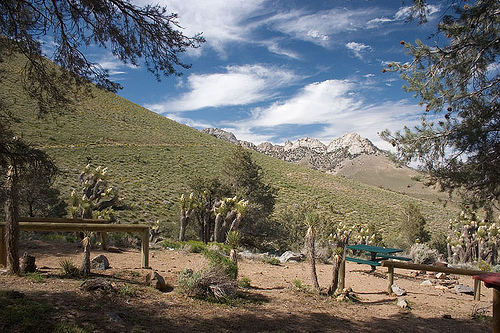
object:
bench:
[340, 244, 412, 271]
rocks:
[420, 278, 437, 286]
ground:
[5, 235, 494, 330]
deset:
[1, 2, 499, 332]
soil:
[0, 235, 498, 332]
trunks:
[298, 223, 348, 299]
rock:
[278, 249, 304, 264]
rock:
[390, 281, 408, 294]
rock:
[144, 271, 165, 288]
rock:
[89, 254, 109, 272]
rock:
[452, 284, 473, 294]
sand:
[104, 246, 492, 301]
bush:
[171, 248, 244, 303]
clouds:
[186, 57, 370, 125]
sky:
[0, 2, 498, 162]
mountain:
[273, 138, 328, 172]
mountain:
[325, 131, 372, 163]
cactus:
[75, 161, 120, 204]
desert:
[0, 41, 499, 331]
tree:
[194, 175, 233, 246]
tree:
[224, 139, 278, 241]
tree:
[398, 200, 437, 260]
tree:
[1, 0, 208, 174]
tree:
[379, 1, 499, 208]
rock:
[114, 263, 143, 278]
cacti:
[302, 225, 348, 295]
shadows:
[4, 264, 495, 330]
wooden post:
[14, 220, 153, 275]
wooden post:
[381, 259, 486, 302]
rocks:
[337, 288, 357, 304]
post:
[12, 208, 151, 273]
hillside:
[0, 36, 467, 250]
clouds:
[245, 6, 475, 66]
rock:
[395, 296, 410, 307]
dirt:
[4, 226, 496, 331]